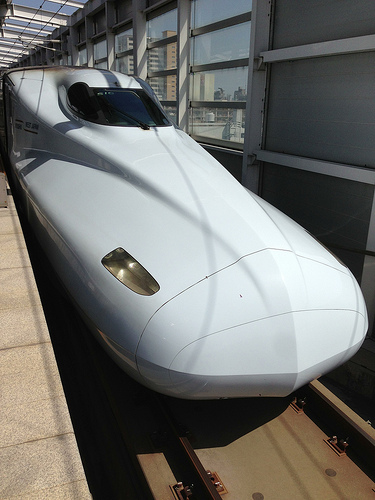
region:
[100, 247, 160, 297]
headlight on this japanese subway train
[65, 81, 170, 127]
windshield that is similar to the batmobile's windshield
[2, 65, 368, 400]
white subway train that looks like a platapus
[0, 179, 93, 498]
side of the landing where you get on and off the subway train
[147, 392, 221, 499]
left side of the tracks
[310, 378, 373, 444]
right side of the tracks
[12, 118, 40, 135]
name of the subway train and logo in japanese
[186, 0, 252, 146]
odd window with metal trim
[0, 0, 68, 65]
electrical wires that power the train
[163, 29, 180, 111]
very tall building outside the windows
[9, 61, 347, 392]
Front of bullet train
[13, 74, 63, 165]
This train is Japanese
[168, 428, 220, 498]
Track beneath train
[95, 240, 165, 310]
Headlight on front of train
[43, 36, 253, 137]
Windows behind train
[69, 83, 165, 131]
Black windshield of train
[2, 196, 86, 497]
Concrete tiles beside train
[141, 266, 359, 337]
Grooves on front of train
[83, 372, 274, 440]
Train's shadow is black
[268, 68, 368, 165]
Gray paneling on wall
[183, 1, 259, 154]
window in a train station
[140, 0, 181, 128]
window in a train station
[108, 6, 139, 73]
window in a train station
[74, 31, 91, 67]
window in a train station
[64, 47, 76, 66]
window in a train station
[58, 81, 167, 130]
windshield on a train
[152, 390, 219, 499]
metal rail road track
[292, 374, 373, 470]
metal rail road track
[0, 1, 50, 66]
metal suspension line in train station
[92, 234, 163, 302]
the light on the side of the vehicle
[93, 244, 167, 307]
light on the white vehicle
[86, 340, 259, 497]
brown rail road track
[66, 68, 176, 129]
front window of white vehicle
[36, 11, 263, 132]
windows on the right of the vehicle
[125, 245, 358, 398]
nose of the vehicle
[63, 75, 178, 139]
the black tented window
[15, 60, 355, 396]
a white vehicle that looks like a train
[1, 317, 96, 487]
the side walk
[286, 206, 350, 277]
spot where right headlight would be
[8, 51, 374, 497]
train on the tracks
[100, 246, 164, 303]
light on the front of the train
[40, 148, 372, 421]
nose of the train is long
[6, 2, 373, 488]
train in the station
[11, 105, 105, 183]
shadow on the train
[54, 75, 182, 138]
dark windows on the front of the train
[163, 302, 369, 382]
thin black line on the front of the train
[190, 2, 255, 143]
row of four windows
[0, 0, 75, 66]
windows on the ceiling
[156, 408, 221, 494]
steel rod on the train track